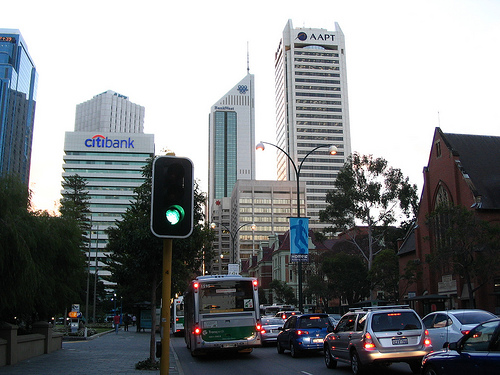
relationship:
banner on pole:
[286, 216, 311, 263] [293, 156, 306, 314]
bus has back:
[175, 271, 268, 354] [192, 268, 265, 355]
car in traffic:
[271, 307, 341, 361] [188, 268, 485, 364]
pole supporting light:
[257, 138, 338, 321] [150, 155, 195, 239]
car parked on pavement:
[325, 301, 434, 371] [176, 330, 360, 372]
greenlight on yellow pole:
[166, 206, 185, 227] [158, 236, 173, 372]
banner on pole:
[284, 216, 311, 265] [253, 135, 340, 317]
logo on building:
[72, 133, 161, 158] [57, 131, 157, 315]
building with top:
[206, 41, 256, 226] [210, 72, 253, 102]